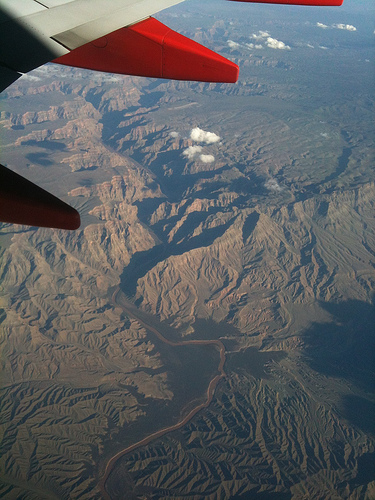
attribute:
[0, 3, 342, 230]
plane — white, orange, whtie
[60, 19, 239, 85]
engine — red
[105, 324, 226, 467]
river — brown, muddy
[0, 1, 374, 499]
sky — white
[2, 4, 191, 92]
wing — red, large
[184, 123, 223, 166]
cloud — whtie, small, floating, few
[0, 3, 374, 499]
ground — brown, bumpy, green, barren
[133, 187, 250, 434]
trail — brown